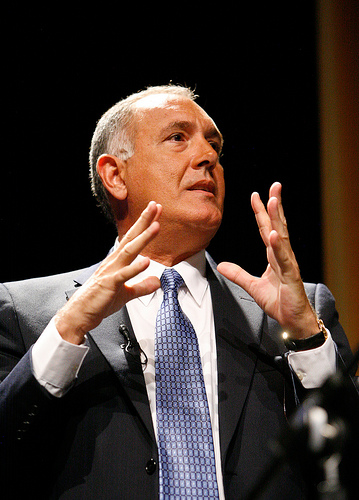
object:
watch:
[284, 325, 318, 349]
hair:
[88, 81, 183, 210]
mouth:
[182, 176, 217, 197]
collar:
[116, 247, 217, 302]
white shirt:
[121, 248, 227, 498]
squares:
[195, 420, 201, 429]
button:
[32, 398, 43, 411]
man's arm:
[0, 297, 101, 462]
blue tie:
[151, 268, 219, 499]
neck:
[124, 227, 216, 276]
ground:
[138, 152, 242, 205]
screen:
[27, 17, 356, 248]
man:
[0, 79, 358, 498]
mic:
[114, 320, 147, 363]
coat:
[0, 235, 355, 498]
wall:
[315, 11, 355, 351]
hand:
[216, 181, 316, 333]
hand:
[52, 200, 162, 334]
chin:
[171, 201, 223, 233]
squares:
[165, 321, 178, 334]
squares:
[186, 441, 193, 450]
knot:
[122, 271, 205, 350]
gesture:
[50, 187, 310, 343]